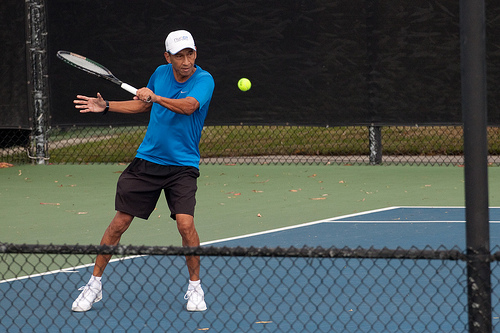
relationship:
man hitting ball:
[68, 25, 218, 318] [233, 73, 255, 95]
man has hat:
[68, 25, 218, 318] [158, 27, 201, 58]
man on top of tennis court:
[68, 25, 218, 318] [3, 164, 499, 333]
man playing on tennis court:
[68, 25, 218, 318] [3, 164, 499, 333]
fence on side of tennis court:
[2, 237, 499, 329] [3, 164, 499, 333]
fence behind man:
[1, 1, 500, 168] [68, 25, 218, 318]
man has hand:
[68, 25, 218, 318] [133, 86, 159, 108]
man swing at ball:
[68, 25, 218, 318] [233, 73, 255, 95]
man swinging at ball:
[68, 25, 218, 318] [233, 73, 255, 95]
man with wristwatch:
[68, 25, 218, 318] [103, 98, 112, 114]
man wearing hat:
[68, 25, 218, 318] [158, 27, 201, 58]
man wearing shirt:
[68, 25, 218, 318] [132, 63, 216, 172]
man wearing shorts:
[68, 25, 218, 318] [114, 157, 203, 221]